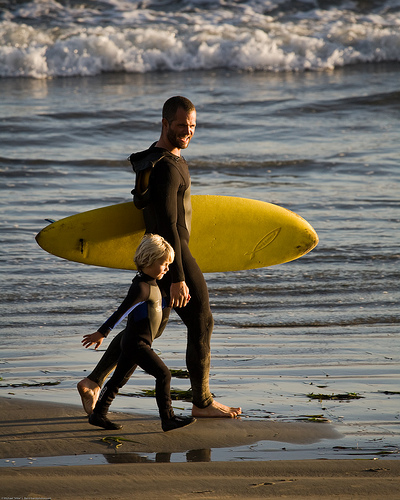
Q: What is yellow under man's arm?
A: Surfboard.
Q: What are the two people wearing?
A: Wetsuits.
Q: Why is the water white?
A: Crashed wave.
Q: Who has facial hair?
A: Adult man.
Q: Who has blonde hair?
A: Child.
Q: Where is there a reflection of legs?
A: Water on sand.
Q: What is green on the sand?
A: Seaweed.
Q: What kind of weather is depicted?
A: Bright and sunny.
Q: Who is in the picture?
A: A man and a boy.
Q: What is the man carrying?
A: Surfboard.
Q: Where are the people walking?
A: On the beach.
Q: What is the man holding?
A: Surfboard.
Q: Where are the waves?
A: In the ocean.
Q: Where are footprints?
A: On the sand.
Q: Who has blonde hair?
A: Young boy.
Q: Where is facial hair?
A: On man's face.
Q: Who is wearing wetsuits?
A: Man and boy.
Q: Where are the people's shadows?
A: On the sand.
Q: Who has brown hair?
A: The man.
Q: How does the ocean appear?
A: Rough.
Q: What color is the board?
A: Yellow.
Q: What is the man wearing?
A: A wetsuit.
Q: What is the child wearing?
A: Water shoes and a wetsuit.